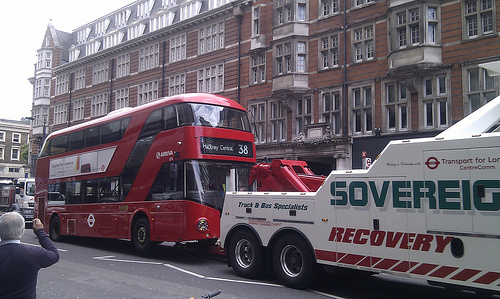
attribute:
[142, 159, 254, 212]
window — clear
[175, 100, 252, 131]
window — clear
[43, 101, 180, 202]
window — clear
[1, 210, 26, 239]
hair — grey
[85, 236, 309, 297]
line — white, long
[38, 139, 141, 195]
sign — side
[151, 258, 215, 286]
lines — white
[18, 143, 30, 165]
tree — green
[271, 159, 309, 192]
mechanism — red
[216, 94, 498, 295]
tow truck — white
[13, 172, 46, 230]
truck — white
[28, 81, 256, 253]
windows — large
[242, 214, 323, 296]
tire — black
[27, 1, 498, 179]
building — bricked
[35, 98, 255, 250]
bus — red,  double decker 